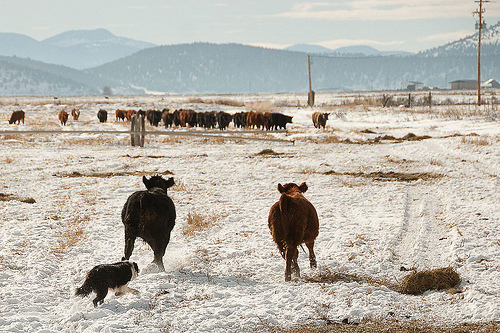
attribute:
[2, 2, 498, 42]
sky — blue, cloudy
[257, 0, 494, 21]
clouds — white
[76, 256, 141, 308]
dog — black, running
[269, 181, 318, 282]
cow — brown, white, running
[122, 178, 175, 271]
cow — black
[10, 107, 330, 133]
cows — herd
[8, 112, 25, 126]
cow — standing